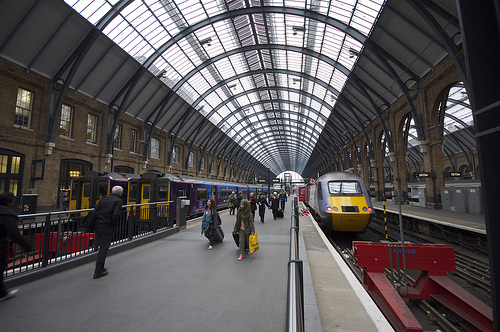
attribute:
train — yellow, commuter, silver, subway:
[301, 170, 376, 234]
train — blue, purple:
[138, 168, 276, 217]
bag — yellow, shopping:
[247, 233, 258, 257]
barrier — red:
[350, 191, 494, 331]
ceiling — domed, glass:
[64, 0, 384, 175]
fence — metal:
[8, 200, 174, 280]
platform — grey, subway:
[5, 192, 292, 331]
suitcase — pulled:
[205, 224, 223, 244]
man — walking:
[90, 185, 126, 279]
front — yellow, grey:
[322, 170, 371, 236]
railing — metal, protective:
[284, 193, 309, 331]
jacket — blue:
[278, 191, 287, 202]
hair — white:
[112, 185, 123, 194]